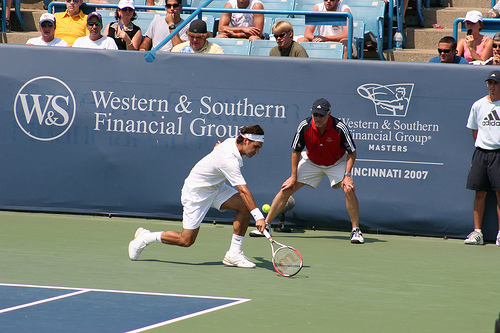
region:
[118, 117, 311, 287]
a man playing tennis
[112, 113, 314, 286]
a professional tennis player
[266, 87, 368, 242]
the linesman at a tennis match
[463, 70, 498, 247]
the ball-boy at a tennis match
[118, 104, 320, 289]
a tennis player hitting a tennis ball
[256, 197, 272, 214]
a yellow tennis ball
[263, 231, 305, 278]
a Wilson tennis racket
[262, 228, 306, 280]
a red and white tennis racket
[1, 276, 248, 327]
a blue and white tennis court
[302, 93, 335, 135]
a man wearing a hat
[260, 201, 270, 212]
a small green tennis ball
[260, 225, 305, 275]
a red, white and black racket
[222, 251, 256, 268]
a man's white tennis shoe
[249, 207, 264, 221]
a white wristband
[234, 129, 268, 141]
a white headband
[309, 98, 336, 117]
a black baseball cap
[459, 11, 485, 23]
a white baseball cap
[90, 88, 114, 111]
a large white capital letter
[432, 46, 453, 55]
dark black sunglasses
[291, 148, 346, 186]
a man's white shorts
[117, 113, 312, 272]
man playing tennis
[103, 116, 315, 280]
man trying to hit the tennis ball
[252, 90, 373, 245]
man watching tennis player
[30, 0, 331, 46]
spectators watching tennis game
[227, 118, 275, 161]
white sweatband around man's head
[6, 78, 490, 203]
blue banner with company logos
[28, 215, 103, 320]
tennis court is blue, white and green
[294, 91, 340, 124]
man wearing a blue addidas baseball hat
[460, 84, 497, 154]
man wearing an addidas t-shirt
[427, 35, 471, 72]
spectator wearing sunglasses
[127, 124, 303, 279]
a male tennis player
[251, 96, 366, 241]
a man standing on tennis court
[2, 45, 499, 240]
a blue stadium banner advertisement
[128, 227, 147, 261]
a white tennis shoe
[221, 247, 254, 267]
a white tennis shoe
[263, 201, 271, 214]
a yellow tennis ball in flight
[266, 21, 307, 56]
a man seated in stands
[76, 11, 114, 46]
a man seated in stands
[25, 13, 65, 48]
a man seated in stands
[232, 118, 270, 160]
the head of a man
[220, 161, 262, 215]
the arm of a man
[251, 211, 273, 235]
the hand of a man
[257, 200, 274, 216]
a green tennis ball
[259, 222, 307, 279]
a tennis racket in the man's hand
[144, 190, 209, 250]
the leg of a man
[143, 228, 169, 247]
a white sock on the man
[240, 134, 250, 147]
the ear of a man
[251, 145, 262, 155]
the nose of a man